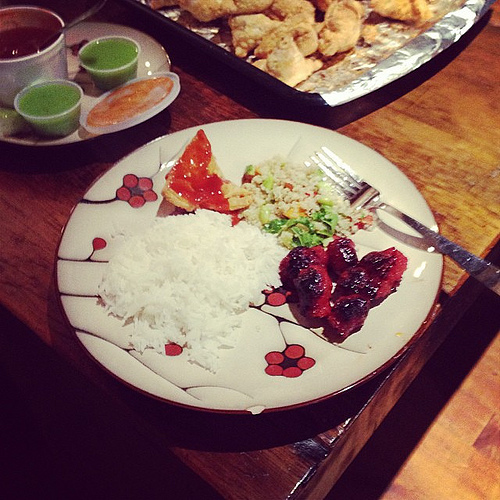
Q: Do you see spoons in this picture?
A: Yes, there is a spoon.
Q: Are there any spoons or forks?
A: Yes, there is a spoon.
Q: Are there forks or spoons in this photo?
A: Yes, there is a spoon.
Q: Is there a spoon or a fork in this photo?
A: Yes, there is a spoon.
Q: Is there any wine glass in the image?
A: No, there are no wine glasses.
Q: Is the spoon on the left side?
A: Yes, the spoon is on the left of the image.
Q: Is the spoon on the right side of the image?
A: No, the spoon is on the left of the image.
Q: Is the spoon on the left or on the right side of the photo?
A: The spoon is on the left of the image.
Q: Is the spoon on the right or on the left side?
A: The spoon is on the left of the image.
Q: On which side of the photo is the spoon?
A: The spoon is on the left of the image.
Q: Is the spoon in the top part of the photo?
A: Yes, the spoon is in the top of the image.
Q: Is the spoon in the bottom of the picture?
A: No, the spoon is in the top of the image.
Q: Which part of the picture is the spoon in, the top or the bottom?
A: The spoon is in the top of the image.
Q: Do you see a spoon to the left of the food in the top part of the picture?
A: Yes, there is a spoon to the left of the food.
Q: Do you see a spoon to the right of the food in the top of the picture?
A: No, the spoon is to the left of the food.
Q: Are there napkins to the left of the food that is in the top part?
A: No, there is a spoon to the left of the food.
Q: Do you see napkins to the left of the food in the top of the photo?
A: No, there is a spoon to the left of the food.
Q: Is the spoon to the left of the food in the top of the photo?
A: Yes, the spoon is to the left of the food.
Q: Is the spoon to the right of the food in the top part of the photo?
A: No, the spoon is to the left of the food.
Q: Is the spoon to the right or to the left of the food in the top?
A: The spoon is to the left of the food.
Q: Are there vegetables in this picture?
A: Yes, there are vegetables.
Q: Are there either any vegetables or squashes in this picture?
A: Yes, there are vegetables.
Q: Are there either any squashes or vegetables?
A: Yes, there are vegetables.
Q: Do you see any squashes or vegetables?
A: Yes, there are vegetables.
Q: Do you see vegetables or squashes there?
A: Yes, there are vegetables.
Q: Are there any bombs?
A: No, there are no bombs.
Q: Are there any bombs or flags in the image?
A: No, there are no bombs or flags.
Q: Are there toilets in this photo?
A: No, there are no toilets.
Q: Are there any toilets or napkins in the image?
A: No, there are no toilets or napkins.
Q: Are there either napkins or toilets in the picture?
A: No, there are no toilets or napkins.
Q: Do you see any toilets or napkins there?
A: No, there are no toilets or napkins.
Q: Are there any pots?
A: No, there are no pots.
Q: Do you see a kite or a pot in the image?
A: No, there are no pots or kites.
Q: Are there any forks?
A: Yes, there is a fork.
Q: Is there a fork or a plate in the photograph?
A: Yes, there is a fork.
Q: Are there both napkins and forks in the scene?
A: No, there is a fork but no napkins.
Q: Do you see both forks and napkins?
A: No, there is a fork but no napkins.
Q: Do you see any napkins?
A: No, there are no napkins.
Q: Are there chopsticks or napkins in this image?
A: No, there are no napkins or chopsticks.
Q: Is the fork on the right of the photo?
A: Yes, the fork is on the right of the image.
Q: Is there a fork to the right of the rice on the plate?
A: Yes, there is a fork to the right of the rice.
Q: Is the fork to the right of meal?
A: No, the fork is to the right of the rice.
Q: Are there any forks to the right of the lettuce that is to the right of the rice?
A: Yes, there is a fork to the right of the lettuce.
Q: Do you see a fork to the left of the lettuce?
A: No, the fork is to the right of the lettuce.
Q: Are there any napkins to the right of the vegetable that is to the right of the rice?
A: No, there is a fork to the right of the lettuce.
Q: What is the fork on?
A: The fork is on the plate.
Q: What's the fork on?
A: The fork is on the plate.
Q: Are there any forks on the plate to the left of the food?
A: Yes, there is a fork on the plate.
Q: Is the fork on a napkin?
A: No, the fork is on the plate.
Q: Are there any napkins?
A: No, there are no napkins.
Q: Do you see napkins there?
A: No, there are no napkins.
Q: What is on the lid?
A: The sauce is on the lid.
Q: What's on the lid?
A: The sauce is on the lid.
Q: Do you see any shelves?
A: No, there are no shelves.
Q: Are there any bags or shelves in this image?
A: No, there are no shelves or bags.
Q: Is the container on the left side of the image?
A: Yes, the container is on the left of the image.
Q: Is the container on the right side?
A: No, the container is on the left of the image.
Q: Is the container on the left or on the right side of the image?
A: The container is on the left of the image.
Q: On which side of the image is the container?
A: The container is on the left of the image.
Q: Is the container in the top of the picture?
A: Yes, the container is in the top of the image.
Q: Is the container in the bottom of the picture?
A: No, the container is in the top of the image.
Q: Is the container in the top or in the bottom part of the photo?
A: The container is in the top of the image.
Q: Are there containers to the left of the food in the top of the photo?
A: Yes, there is a container to the left of the food.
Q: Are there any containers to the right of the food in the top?
A: No, the container is to the left of the food.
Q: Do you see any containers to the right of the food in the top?
A: No, the container is to the left of the food.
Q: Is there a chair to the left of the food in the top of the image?
A: No, there is a container to the left of the food.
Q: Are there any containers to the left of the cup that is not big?
A: Yes, there is a container to the left of the cup.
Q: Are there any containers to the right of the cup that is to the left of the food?
A: No, the container is to the left of the cup.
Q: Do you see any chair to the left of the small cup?
A: No, there is a container to the left of the cup.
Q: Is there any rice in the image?
A: Yes, there is rice.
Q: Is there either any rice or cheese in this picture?
A: Yes, there is rice.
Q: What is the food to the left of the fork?
A: The food is rice.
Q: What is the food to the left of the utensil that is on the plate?
A: The food is rice.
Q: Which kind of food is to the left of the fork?
A: The food is rice.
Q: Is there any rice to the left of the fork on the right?
A: Yes, there is rice to the left of the fork.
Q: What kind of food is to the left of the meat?
A: The food is rice.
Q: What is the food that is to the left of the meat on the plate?
A: The food is rice.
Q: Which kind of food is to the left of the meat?
A: The food is rice.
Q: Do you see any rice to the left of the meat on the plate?
A: Yes, there is rice to the left of the meat.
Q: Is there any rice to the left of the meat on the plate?
A: Yes, there is rice to the left of the meat.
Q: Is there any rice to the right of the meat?
A: No, the rice is to the left of the meat.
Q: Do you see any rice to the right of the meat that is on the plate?
A: No, the rice is to the left of the meat.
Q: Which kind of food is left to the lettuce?
A: The food is rice.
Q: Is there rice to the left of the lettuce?
A: Yes, there is rice to the left of the lettuce.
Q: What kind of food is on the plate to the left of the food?
A: The food is rice.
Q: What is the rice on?
A: The rice is on the plate.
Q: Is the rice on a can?
A: No, the rice is on the plate.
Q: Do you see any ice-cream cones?
A: No, there are no ice-cream cones.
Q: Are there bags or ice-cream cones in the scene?
A: No, there are no ice-cream cones or bags.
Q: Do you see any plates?
A: Yes, there is a plate.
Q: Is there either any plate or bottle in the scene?
A: Yes, there is a plate.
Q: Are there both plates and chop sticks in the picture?
A: No, there is a plate but no chopsticks.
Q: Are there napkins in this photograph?
A: No, there are no napkins.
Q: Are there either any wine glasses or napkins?
A: No, there are no napkins or wine glasses.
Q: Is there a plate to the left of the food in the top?
A: Yes, there is a plate to the left of the food.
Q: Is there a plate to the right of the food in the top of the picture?
A: No, the plate is to the left of the food.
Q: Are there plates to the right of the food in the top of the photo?
A: No, the plate is to the left of the food.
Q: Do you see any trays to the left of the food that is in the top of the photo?
A: No, there is a plate to the left of the food.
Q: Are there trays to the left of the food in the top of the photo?
A: No, there is a plate to the left of the food.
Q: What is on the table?
A: The plate is on the table.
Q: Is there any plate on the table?
A: Yes, there is a plate on the table.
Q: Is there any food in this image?
A: Yes, there is food.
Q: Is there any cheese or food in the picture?
A: Yes, there is food.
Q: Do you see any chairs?
A: No, there are no chairs.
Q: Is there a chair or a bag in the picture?
A: No, there are no chairs or bags.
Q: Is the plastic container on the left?
A: Yes, the container is on the left of the image.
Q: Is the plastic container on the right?
A: No, the container is on the left of the image.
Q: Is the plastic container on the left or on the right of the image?
A: The container is on the left of the image.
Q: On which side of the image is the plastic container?
A: The container is on the left of the image.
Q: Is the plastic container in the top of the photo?
A: Yes, the container is in the top of the image.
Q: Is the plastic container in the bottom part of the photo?
A: No, the container is in the top of the image.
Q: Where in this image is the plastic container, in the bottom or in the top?
A: The container is in the top of the image.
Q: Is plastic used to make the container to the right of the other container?
A: Yes, the container is made of plastic.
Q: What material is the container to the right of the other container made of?
A: The container is made of plastic.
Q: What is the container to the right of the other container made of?
A: The container is made of plastic.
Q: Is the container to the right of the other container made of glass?
A: No, the container is made of plastic.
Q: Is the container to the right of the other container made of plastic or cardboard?
A: The container is made of plastic.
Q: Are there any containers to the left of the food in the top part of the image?
A: Yes, there is a container to the left of the food.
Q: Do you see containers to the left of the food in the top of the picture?
A: Yes, there is a container to the left of the food.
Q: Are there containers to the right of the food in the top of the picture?
A: No, the container is to the left of the food.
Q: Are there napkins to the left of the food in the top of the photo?
A: No, there is a container to the left of the food.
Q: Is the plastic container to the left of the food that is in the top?
A: Yes, the container is to the left of the food.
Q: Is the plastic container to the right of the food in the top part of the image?
A: No, the container is to the left of the food.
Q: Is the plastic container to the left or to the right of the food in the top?
A: The container is to the left of the food.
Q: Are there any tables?
A: Yes, there is a table.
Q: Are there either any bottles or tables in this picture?
A: Yes, there is a table.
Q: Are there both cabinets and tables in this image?
A: No, there is a table but no cabinets.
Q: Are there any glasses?
A: No, there are no glasses.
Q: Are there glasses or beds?
A: No, there are no glasses or beds.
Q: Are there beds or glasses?
A: No, there are no glasses or beds.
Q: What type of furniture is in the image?
A: The furniture is a table.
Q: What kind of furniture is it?
A: The piece of furniture is a table.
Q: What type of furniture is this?
A: This is a table.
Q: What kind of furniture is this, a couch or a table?
A: This is a table.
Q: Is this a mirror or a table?
A: This is a table.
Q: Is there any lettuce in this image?
A: Yes, there is lettuce.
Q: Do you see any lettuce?
A: Yes, there is lettuce.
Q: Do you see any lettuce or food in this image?
A: Yes, there is lettuce.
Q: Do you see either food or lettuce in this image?
A: Yes, there is lettuce.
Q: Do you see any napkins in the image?
A: No, there are no napkins.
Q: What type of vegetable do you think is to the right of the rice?
A: The vegetable is lettuce.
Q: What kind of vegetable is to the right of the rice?
A: The vegetable is lettuce.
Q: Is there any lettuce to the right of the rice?
A: Yes, there is lettuce to the right of the rice.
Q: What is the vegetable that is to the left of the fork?
A: The vegetable is lettuce.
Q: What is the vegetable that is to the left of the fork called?
A: The vegetable is lettuce.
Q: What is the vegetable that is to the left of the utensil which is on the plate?
A: The vegetable is lettuce.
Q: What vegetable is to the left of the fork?
A: The vegetable is lettuce.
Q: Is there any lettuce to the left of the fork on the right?
A: Yes, there is lettuce to the left of the fork.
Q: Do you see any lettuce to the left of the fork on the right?
A: Yes, there is lettuce to the left of the fork.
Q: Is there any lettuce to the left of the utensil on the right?
A: Yes, there is lettuce to the left of the fork.